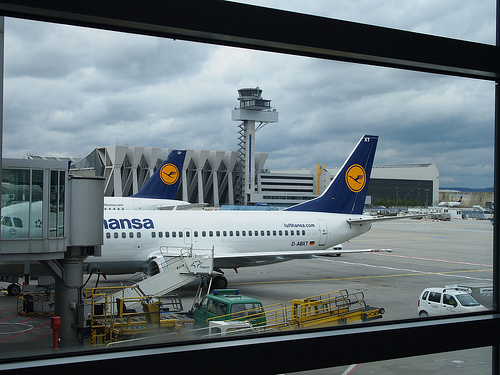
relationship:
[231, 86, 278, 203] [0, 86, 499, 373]
tower in airport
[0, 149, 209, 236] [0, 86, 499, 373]
airplane at airport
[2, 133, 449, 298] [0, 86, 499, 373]
airliner at airport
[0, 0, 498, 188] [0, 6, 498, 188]
clouds in sky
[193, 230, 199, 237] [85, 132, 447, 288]
window on plane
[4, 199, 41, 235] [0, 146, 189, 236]
cockpit on airplane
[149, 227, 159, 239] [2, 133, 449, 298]
window on airliner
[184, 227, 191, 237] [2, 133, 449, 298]
window on airliner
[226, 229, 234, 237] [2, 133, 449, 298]
window on airliner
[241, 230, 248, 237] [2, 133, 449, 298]
window on airliner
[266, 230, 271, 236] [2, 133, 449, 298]
window on airliner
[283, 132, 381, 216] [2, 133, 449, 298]
tail on airliner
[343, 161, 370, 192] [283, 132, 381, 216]
logo on tail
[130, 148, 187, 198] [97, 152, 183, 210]
tail on plane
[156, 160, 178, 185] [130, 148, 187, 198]
logo on tail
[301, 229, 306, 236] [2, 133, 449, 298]
window on airliner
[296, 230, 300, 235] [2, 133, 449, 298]
window on airliner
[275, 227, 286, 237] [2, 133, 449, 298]
window on airliner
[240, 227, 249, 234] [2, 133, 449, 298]
window on airliner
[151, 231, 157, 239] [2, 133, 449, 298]
window on airliner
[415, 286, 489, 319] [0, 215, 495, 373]
car in parking lot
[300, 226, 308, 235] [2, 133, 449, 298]
window on airliner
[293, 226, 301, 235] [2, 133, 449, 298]
window on airliner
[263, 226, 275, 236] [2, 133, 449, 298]
window on airliner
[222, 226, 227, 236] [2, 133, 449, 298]
window on airliner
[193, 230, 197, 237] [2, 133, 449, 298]
window on airliner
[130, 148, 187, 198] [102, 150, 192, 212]
tail on plane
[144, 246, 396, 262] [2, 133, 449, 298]
wing on airliner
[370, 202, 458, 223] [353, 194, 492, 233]
vehicles in parking lot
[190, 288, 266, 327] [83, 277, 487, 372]
luggage truck in parking lot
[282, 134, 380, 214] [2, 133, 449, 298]
tail of airliner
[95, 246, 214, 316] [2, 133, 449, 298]
jetway to airliner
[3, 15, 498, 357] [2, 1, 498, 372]
view from window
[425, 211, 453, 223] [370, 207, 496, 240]
cones on ground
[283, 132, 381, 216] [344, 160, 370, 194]
tail with circle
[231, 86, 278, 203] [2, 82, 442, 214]
tower at airport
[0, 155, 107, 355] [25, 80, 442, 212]
bridge to airport terminal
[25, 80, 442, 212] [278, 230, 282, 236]
airport terminal has window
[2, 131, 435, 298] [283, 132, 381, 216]
airliner has tail